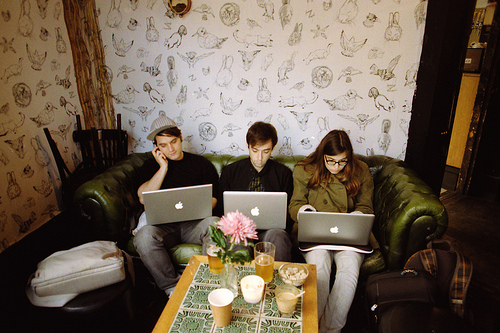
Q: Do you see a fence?
A: No, there are no fences.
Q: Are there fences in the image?
A: No, there are no fences.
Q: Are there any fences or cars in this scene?
A: No, there are no fences or cars.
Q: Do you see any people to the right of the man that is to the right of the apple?
A: Yes, there is a person to the right of the man.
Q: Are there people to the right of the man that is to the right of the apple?
A: Yes, there is a person to the right of the man.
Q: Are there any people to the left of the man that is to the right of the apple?
A: No, the person is to the right of the man.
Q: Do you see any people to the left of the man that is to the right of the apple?
A: No, the person is to the right of the man.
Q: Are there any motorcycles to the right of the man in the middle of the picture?
A: No, there is a person to the right of the man.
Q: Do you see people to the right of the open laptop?
A: Yes, there is a person to the right of the laptop.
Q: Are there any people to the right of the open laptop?
A: Yes, there is a person to the right of the laptop.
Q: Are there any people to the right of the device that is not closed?
A: Yes, there is a person to the right of the laptop.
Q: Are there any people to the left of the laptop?
A: No, the person is to the right of the laptop.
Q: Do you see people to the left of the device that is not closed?
A: No, the person is to the right of the laptop.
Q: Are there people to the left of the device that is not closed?
A: No, the person is to the right of the laptop.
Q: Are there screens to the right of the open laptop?
A: No, there is a person to the right of the laptop.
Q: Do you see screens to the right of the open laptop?
A: No, there is a person to the right of the laptop.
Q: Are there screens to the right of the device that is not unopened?
A: No, there is a person to the right of the laptop.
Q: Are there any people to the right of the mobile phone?
A: Yes, there is a person to the right of the mobile phone.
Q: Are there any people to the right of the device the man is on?
A: Yes, there is a person to the right of the mobile phone.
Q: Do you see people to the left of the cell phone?
A: No, the person is to the right of the cell phone.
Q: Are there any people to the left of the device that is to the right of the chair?
A: No, the person is to the right of the cell phone.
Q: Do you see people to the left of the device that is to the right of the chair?
A: No, the person is to the right of the cell phone.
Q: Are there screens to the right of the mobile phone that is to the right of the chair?
A: No, there is a person to the right of the cellphone.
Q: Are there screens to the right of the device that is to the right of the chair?
A: No, there is a person to the right of the cellphone.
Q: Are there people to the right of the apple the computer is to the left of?
A: Yes, there is a person to the right of the apple.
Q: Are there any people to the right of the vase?
A: Yes, there is a person to the right of the vase.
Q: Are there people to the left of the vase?
A: No, the person is to the right of the vase.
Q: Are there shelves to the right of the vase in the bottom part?
A: No, there is a person to the right of the vase.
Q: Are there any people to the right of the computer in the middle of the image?
A: Yes, there is a person to the right of the computer.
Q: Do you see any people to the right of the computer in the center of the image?
A: Yes, there is a person to the right of the computer.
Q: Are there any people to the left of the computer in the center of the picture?
A: No, the person is to the right of the computer.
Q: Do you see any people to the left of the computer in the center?
A: No, the person is to the right of the computer.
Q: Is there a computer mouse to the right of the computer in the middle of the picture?
A: No, there is a person to the right of the computer.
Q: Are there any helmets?
A: No, there are no helmets.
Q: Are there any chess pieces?
A: No, there are no chess pieces.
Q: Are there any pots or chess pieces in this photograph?
A: No, there are no chess pieces or pots.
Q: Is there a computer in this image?
A: Yes, there is a computer.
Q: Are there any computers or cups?
A: Yes, there is a computer.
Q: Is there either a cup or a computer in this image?
A: Yes, there is a computer.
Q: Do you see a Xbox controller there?
A: No, there are no Xbox controllers.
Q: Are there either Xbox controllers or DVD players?
A: No, there are no Xbox controllers or DVD players.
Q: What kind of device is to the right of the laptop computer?
A: The device is a computer.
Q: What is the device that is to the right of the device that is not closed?
A: The device is a computer.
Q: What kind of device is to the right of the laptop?
A: The device is a computer.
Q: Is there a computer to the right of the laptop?
A: Yes, there is a computer to the right of the laptop.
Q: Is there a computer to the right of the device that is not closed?
A: Yes, there is a computer to the right of the laptop.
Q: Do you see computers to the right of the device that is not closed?
A: Yes, there is a computer to the right of the laptop.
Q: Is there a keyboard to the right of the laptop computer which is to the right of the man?
A: No, there is a computer to the right of the laptop computer.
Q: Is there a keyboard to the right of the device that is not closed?
A: No, there is a computer to the right of the laptop computer.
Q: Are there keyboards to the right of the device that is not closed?
A: No, there is a computer to the right of the laptop computer.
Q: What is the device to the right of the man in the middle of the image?
A: The device is a computer.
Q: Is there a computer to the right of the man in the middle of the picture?
A: Yes, there is a computer to the right of the man.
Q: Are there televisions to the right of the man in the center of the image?
A: No, there is a computer to the right of the man.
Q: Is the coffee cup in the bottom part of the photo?
A: Yes, the coffee cup is in the bottom of the image.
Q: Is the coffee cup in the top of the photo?
A: No, the coffee cup is in the bottom of the image.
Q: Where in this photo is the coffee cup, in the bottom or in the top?
A: The coffee cup is in the bottom of the image.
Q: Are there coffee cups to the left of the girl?
A: Yes, there is a coffee cup to the left of the girl.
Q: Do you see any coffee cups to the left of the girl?
A: Yes, there is a coffee cup to the left of the girl.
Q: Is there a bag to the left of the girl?
A: No, there is a coffee cup to the left of the girl.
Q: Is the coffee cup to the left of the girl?
A: Yes, the coffee cup is to the left of the girl.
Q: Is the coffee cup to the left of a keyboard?
A: No, the coffee cup is to the left of the girl.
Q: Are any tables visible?
A: Yes, there is a table.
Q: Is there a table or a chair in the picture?
A: Yes, there is a table.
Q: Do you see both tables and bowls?
A: Yes, there are both a table and a bowl.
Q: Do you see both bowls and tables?
A: Yes, there are both a table and a bowl.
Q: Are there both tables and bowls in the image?
A: Yes, there are both a table and a bowl.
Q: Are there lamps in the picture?
A: No, there are no lamps.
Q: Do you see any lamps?
A: No, there are no lamps.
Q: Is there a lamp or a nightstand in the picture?
A: No, there are no lamps or nightstands.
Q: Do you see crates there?
A: No, there are no crates.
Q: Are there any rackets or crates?
A: No, there are no crates or rackets.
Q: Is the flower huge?
A: Yes, the flower is huge.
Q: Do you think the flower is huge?
A: Yes, the flower is huge.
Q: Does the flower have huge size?
A: Yes, the flower is huge.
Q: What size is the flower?
A: The flower is huge.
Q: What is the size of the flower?
A: The flower is huge.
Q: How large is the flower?
A: The flower is huge.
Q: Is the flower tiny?
A: No, the flower is huge.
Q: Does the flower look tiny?
A: No, the flower is huge.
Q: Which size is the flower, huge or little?
A: The flower is huge.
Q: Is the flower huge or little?
A: The flower is huge.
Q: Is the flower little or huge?
A: The flower is huge.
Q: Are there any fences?
A: No, there are no fences.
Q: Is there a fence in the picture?
A: No, there are no fences.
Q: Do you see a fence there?
A: No, there are no fences.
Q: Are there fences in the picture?
A: No, there are no fences.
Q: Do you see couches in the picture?
A: Yes, there is a couch.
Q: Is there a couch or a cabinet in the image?
A: Yes, there is a couch.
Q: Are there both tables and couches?
A: Yes, there are both a couch and a table.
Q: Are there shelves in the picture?
A: No, there are no shelves.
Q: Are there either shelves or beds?
A: No, there are no shelves or beds.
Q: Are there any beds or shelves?
A: No, there are no shelves or beds.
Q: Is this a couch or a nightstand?
A: This is a couch.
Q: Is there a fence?
A: No, there are no fences.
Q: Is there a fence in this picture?
A: No, there are no fences.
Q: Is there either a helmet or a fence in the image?
A: No, there are no helmets or fences.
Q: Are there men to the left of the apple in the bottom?
A: Yes, there is a man to the left of the apple.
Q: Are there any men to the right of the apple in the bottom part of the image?
A: No, the man is to the left of the apple.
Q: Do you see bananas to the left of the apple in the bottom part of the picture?
A: No, there is a man to the left of the apple.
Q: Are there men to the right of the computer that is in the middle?
A: Yes, there is a man to the right of the computer.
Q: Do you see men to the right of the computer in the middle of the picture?
A: Yes, there is a man to the right of the computer.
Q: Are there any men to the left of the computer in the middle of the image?
A: No, the man is to the right of the computer.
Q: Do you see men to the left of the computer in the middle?
A: No, the man is to the right of the computer.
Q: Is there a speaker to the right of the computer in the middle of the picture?
A: No, there is a man to the right of the computer.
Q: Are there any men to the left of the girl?
A: Yes, there is a man to the left of the girl.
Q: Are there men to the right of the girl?
A: No, the man is to the left of the girl.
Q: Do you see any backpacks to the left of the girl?
A: No, there is a man to the left of the girl.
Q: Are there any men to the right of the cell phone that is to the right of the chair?
A: Yes, there is a man to the right of the cellphone.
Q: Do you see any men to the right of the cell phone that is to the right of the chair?
A: Yes, there is a man to the right of the cellphone.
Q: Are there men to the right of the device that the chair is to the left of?
A: Yes, there is a man to the right of the cellphone.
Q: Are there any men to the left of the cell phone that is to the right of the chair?
A: No, the man is to the right of the cell phone.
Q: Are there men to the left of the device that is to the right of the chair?
A: No, the man is to the right of the cell phone.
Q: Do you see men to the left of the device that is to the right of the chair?
A: No, the man is to the right of the cell phone.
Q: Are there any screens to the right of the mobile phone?
A: No, there is a man to the right of the mobile phone.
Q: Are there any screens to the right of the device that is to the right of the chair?
A: No, there is a man to the right of the mobile phone.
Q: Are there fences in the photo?
A: No, there are no fences.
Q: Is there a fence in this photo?
A: No, there are no fences.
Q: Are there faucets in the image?
A: No, there are no faucets.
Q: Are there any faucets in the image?
A: No, there are no faucets.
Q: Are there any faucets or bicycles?
A: No, there are no faucets or bicycles.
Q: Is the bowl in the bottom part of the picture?
A: Yes, the bowl is in the bottom of the image.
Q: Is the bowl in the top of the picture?
A: No, the bowl is in the bottom of the image.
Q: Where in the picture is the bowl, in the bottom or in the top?
A: The bowl is in the bottom of the image.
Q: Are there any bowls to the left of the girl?
A: Yes, there is a bowl to the left of the girl.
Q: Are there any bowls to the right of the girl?
A: No, the bowl is to the left of the girl.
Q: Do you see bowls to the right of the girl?
A: No, the bowl is to the left of the girl.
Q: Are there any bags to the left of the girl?
A: No, there is a bowl to the left of the girl.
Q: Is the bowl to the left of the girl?
A: Yes, the bowl is to the left of the girl.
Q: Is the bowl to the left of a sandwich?
A: No, the bowl is to the left of the girl.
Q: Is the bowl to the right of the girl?
A: No, the bowl is to the left of the girl.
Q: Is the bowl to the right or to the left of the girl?
A: The bowl is to the left of the girl.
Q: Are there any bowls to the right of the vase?
A: Yes, there is a bowl to the right of the vase.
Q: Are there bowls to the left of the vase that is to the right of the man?
A: No, the bowl is to the right of the vase.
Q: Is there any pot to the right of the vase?
A: No, there is a bowl to the right of the vase.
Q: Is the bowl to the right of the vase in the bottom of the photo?
A: Yes, the bowl is to the right of the vase.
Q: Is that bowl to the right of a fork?
A: No, the bowl is to the right of the vase.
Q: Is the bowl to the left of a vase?
A: No, the bowl is to the right of a vase.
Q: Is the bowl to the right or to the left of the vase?
A: The bowl is to the right of the vase.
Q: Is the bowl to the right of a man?
A: Yes, the bowl is to the right of a man.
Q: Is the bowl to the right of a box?
A: No, the bowl is to the right of a man.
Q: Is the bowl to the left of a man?
A: No, the bowl is to the right of a man.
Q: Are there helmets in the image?
A: No, there are no helmets.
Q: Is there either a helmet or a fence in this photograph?
A: No, there are no helmets or fences.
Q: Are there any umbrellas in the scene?
A: No, there are no umbrellas.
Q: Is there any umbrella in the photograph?
A: No, there are no umbrellas.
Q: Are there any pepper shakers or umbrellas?
A: No, there are no umbrellas or pepper shakers.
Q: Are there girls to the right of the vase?
A: Yes, there is a girl to the right of the vase.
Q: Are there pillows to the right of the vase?
A: No, there is a girl to the right of the vase.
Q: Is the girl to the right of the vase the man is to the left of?
A: Yes, the girl is to the right of the vase.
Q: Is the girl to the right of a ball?
A: No, the girl is to the right of the vase.